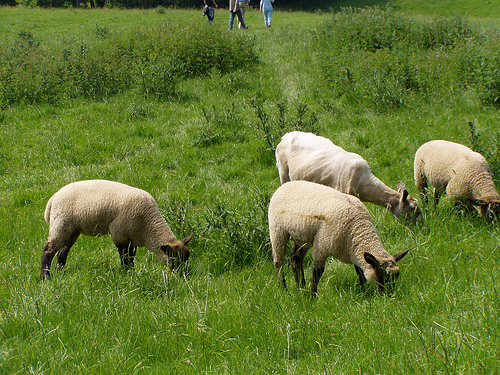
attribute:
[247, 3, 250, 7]
frisbee — red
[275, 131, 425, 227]
sheep — white, skinny, soft, eating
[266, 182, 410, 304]
sheep — grazing, marked, white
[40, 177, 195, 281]
sheep — white, eating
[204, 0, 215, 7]
shirt — black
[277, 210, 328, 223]
mark — green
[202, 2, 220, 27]
person — walking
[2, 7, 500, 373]
field — grassy, green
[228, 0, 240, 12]
shirt — gray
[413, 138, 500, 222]
sheep — white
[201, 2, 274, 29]
people — walking